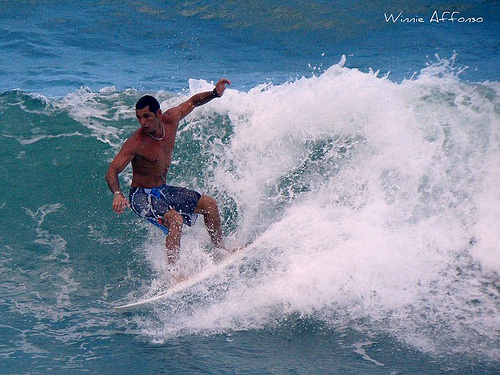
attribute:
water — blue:
[3, 1, 498, 373]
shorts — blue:
[128, 185, 198, 234]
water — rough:
[268, 70, 369, 218]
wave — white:
[225, 58, 499, 296]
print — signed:
[327, 6, 495, 46]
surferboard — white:
[67, 207, 327, 320]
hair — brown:
[136, 92, 158, 112]